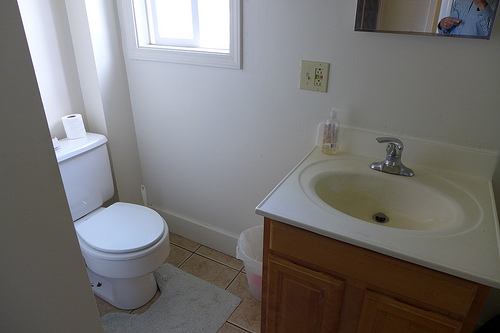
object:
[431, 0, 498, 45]
person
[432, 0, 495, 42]
blue shirt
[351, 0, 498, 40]
bathroom mirror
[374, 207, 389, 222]
stopper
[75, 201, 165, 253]
lid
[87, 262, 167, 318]
base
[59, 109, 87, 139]
tissue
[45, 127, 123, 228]
toilet tank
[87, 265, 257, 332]
mat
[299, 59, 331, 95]
outlet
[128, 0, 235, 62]
window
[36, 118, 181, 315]
toilet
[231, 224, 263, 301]
basket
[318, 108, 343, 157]
bottle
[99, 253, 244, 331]
rug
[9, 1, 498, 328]
bathroom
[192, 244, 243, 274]
tile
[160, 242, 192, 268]
tile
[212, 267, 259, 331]
tile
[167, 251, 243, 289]
tile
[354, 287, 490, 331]
cabinet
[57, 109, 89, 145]
roll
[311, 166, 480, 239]
sink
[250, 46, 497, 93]
wall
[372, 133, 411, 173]
faucet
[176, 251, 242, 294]
beige tile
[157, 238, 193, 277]
beige tile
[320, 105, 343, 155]
soap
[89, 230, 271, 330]
floor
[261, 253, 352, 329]
cabinets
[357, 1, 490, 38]
reflection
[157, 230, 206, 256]
tile